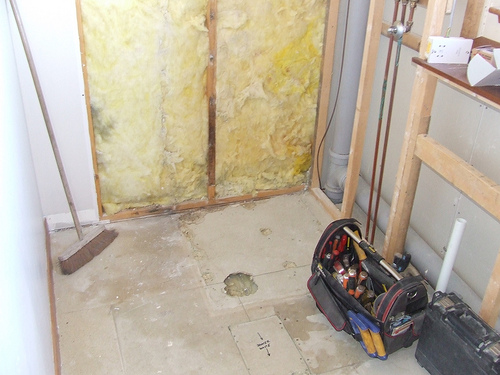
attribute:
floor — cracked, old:
[48, 191, 422, 374]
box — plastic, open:
[308, 216, 429, 345]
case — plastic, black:
[414, 289, 499, 373]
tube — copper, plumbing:
[362, 0, 403, 247]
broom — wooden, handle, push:
[11, 0, 117, 272]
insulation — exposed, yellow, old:
[83, 3, 216, 214]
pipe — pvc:
[430, 211, 468, 294]